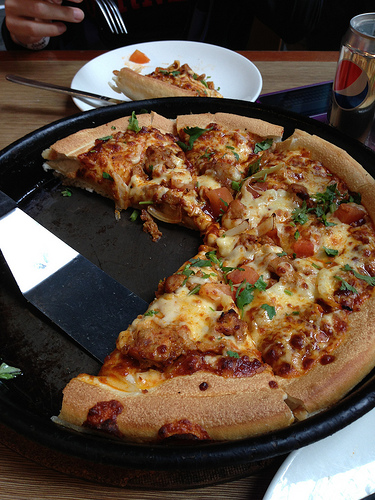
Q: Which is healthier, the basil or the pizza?
A: The basil is healthier than the pizza.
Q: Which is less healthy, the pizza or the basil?
A: The pizza is less healthy than the basil.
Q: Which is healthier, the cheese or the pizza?
A: The cheese is healthier than the pizza.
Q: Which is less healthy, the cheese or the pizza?
A: The pizza is less healthy than the cheese.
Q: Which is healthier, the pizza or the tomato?
A: The tomato is healthier than the pizza.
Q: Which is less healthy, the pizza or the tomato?
A: The pizza is less healthy than the tomato.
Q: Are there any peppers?
A: No, there are no peppers.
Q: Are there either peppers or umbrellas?
A: No, there are no peppers or umbrellas.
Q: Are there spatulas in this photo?
A: Yes, there is a spatula.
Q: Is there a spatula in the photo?
A: Yes, there is a spatula.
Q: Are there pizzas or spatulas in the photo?
A: Yes, there is a spatula.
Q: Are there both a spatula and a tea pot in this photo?
A: No, there is a spatula but no tea pots.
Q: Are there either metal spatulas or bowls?
A: Yes, there is a metal spatula.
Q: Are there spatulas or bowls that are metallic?
A: Yes, the spatula is metallic.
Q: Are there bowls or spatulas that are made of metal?
A: Yes, the spatula is made of metal.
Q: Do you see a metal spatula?
A: Yes, there is a metal spatula.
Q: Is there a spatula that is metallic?
A: Yes, there is a spatula that is metallic.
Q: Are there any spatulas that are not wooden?
A: Yes, there is a metallic spatula.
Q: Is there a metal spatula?
A: Yes, there is a spatula that is made of metal.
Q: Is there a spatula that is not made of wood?
A: Yes, there is a spatula that is made of metal.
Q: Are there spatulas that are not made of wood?
A: Yes, there is a spatula that is made of metal.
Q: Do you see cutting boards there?
A: No, there are no cutting boards.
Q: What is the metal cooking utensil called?
A: The cooking utensil is a spatula.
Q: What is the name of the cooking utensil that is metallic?
A: The cooking utensil is a spatula.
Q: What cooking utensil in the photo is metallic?
A: The cooking utensil is a spatula.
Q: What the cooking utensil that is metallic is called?
A: The cooking utensil is a spatula.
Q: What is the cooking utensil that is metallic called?
A: The cooking utensil is a spatula.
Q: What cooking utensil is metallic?
A: The cooking utensil is a spatula.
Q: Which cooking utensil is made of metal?
A: The cooking utensil is a spatula.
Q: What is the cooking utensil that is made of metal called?
A: The cooking utensil is a spatula.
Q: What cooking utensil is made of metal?
A: The cooking utensil is a spatula.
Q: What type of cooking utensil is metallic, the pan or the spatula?
A: The spatula is metallic.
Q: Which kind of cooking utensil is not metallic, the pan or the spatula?
A: The pan is not metallic.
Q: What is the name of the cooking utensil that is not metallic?
A: The cooking utensil is a pan.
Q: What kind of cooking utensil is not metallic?
A: The cooking utensil is a pan.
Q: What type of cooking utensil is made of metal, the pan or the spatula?
A: The spatula is made of metal.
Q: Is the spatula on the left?
A: Yes, the spatula is on the left of the image.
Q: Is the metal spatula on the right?
A: No, the spatula is on the left of the image.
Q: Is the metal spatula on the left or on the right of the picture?
A: The spatula is on the left of the image.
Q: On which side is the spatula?
A: The spatula is on the left of the image.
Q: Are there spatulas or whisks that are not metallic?
A: No, there is a spatula but it is metallic.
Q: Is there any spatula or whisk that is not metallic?
A: No, there is a spatula but it is metallic.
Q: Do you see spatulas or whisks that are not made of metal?
A: No, there is a spatula but it is made of metal.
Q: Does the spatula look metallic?
A: Yes, the spatula is metallic.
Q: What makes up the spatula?
A: The spatula is made of metal.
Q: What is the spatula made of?
A: The spatula is made of metal.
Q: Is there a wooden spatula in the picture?
A: No, there is a spatula but it is metallic.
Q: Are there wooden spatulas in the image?
A: No, there is a spatula but it is metallic.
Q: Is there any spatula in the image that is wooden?
A: No, there is a spatula but it is metallic.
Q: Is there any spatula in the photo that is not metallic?
A: No, there is a spatula but it is metallic.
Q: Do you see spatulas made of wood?
A: No, there is a spatula but it is made of metal.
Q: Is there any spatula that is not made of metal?
A: No, there is a spatula but it is made of metal.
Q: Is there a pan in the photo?
A: Yes, there is a pan.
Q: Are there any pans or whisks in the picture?
A: Yes, there is a pan.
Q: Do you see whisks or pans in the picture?
A: Yes, there is a pan.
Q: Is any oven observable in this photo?
A: No, there are no ovens.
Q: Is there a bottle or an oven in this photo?
A: No, there are no ovens or bottles.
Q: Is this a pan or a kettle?
A: This is a pan.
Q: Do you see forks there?
A: Yes, there is a fork.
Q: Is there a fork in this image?
A: Yes, there is a fork.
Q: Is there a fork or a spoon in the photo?
A: Yes, there is a fork.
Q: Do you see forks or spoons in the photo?
A: Yes, there is a fork.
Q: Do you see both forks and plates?
A: Yes, there are both a fork and a plate.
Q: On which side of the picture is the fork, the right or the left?
A: The fork is on the left of the image.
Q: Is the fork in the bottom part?
A: No, the fork is in the top of the image.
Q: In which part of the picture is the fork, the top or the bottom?
A: The fork is in the top of the image.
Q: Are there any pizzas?
A: Yes, there is a pizza.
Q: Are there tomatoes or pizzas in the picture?
A: Yes, there is a pizza.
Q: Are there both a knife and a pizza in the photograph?
A: Yes, there are both a pizza and a knife.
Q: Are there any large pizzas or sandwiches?
A: Yes, there is a large pizza.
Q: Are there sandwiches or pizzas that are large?
A: Yes, the pizza is large.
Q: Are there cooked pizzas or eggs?
A: Yes, there is a cooked pizza.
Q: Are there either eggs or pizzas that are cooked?
A: Yes, the pizza is cooked.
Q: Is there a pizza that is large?
A: Yes, there is a large pizza.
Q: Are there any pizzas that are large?
A: Yes, there is a pizza that is large.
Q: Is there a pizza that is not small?
A: Yes, there is a large pizza.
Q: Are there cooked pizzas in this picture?
A: Yes, there is a cooked pizza.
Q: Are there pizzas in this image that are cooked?
A: Yes, there is a pizza that is cooked.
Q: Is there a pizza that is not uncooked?
A: Yes, there is an cooked pizza.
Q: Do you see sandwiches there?
A: No, there are no sandwiches.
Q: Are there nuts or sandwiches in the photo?
A: No, there are no sandwiches or nuts.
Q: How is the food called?
A: The food is a pizza.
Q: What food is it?
A: The food is a pizza.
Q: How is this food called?
A: This is a pizza.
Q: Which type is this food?
A: This is a pizza.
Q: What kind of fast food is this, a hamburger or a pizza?
A: This is a pizza.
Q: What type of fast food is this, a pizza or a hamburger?
A: This is a pizza.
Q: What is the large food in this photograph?
A: The food is a pizza.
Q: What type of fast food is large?
A: The fast food is a pizza.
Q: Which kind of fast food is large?
A: The fast food is a pizza.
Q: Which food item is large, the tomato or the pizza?
A: The pizza is large.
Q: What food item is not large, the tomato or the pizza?
A: The tomato is not large.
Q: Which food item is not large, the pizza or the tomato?
A: The tomato is not large.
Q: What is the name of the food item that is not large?
A: The food item is a tomato.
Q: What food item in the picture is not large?
A: The food item is a tomato.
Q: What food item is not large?
A: The food item is a tomato.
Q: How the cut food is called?
A: The food is a pizza.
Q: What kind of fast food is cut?
A: The fast food is a pizza.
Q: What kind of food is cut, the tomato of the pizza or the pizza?
A: The pizza is cut.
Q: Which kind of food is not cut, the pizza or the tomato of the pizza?
A: The tomato is not cut.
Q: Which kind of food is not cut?
A: The food is a tomato.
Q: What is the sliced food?
A: The food is a pizza.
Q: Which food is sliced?
A: The food is a pizza.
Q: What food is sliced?
A: The food is a pizza.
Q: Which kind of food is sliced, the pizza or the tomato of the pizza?
A: The pizza is sliced.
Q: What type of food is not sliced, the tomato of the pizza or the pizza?
A: The tomato is not sliced.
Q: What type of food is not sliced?
A: The food is a tomato.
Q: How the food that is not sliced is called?
A: The food is a tomato.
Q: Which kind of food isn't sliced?
A: The food is a tomato.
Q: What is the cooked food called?
A: The food is a pizza.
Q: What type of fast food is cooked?
A: The fast food is a pizza.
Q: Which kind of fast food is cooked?
A: The fast food is a pizza.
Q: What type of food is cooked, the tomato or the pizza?
A: The pizza is cooked.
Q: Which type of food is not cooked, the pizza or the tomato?
A: The tomato is not cooked.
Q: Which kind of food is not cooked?
A: The food is a tomato.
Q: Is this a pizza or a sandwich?
A: This is a pizza.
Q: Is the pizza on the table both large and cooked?
A: Yes, the pizza is large and cooked.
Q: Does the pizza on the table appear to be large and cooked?
A: Yes, the pizza is large and cooked.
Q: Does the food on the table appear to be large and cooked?
A: Yes, the pizza is large and cooked.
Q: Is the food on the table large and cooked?
A: Yes, the pizza is large and cooked.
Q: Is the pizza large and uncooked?
A: No, the pizza is large but cooked.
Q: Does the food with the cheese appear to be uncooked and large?
A: No, the pizza is large but cooked.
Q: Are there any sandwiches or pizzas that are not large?
A: No, there is a pizza but it is large.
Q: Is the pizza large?
A: Yes, the pizza is large.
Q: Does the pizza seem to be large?
A: Yes, the pizza is large.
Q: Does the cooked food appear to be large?
A: Yes, the pizza is large.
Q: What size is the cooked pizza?
A: The pizza is large.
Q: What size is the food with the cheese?
A: The pizza is large.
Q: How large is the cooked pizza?
A: The pizza is large.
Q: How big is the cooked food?
A: The pizza is large.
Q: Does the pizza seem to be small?
A: No, the pizza is large.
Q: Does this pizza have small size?
A: No, the pizza is large.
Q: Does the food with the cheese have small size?
A: No, the pizza is large.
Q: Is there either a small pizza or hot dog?
A: No, there is a pizza but it is large.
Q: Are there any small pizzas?
A: No, there is a pizza but it is large.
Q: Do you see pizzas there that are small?
A: No, there is a pizza but it is large.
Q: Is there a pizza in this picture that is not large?
A: No, there is a pizza but it is large.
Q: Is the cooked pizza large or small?
A: The pizza is large.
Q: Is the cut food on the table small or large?
A: The pizza is large.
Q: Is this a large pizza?
A: Yes, this is a large pizza.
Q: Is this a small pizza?
A: No, this is a large pizza.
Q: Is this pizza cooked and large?
A: Yes, the pizza is cooked and large.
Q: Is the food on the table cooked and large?
A: Yes, the pizza is cooked and large.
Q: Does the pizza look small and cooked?
A: No, the pizza is cooked but large.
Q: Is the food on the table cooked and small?
A: No, the pizza is cooked but large.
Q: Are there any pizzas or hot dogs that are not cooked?
A: No, there is a pizza but it is cooked.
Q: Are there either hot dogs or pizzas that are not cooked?
A: No, there is a pizza but it is cooked.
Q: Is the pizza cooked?
A: Yes, the pizza is cooked.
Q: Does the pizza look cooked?
A: Yes, the pizza is cooked.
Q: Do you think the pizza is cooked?
A: Yes, the pizza is cooked.